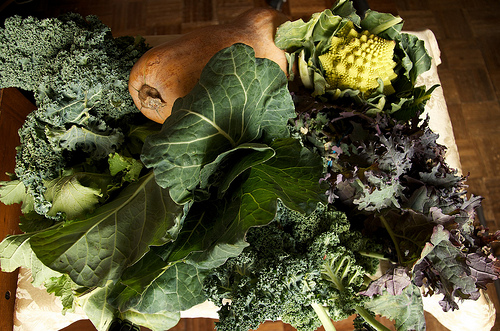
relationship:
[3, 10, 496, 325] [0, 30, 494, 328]
vegetables on table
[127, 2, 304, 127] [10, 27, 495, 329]
pumpkin on plate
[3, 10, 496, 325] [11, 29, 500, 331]
vegetables on fabric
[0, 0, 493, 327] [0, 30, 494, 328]
table on table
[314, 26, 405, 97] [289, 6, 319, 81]
vegetable and leaves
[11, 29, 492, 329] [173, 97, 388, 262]
fabric under vegetable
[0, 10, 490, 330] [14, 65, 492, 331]
garden from a garden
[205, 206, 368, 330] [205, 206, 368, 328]
broccoli portion of broccoli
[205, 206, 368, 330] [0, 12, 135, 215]
broccoli portion of broccoli